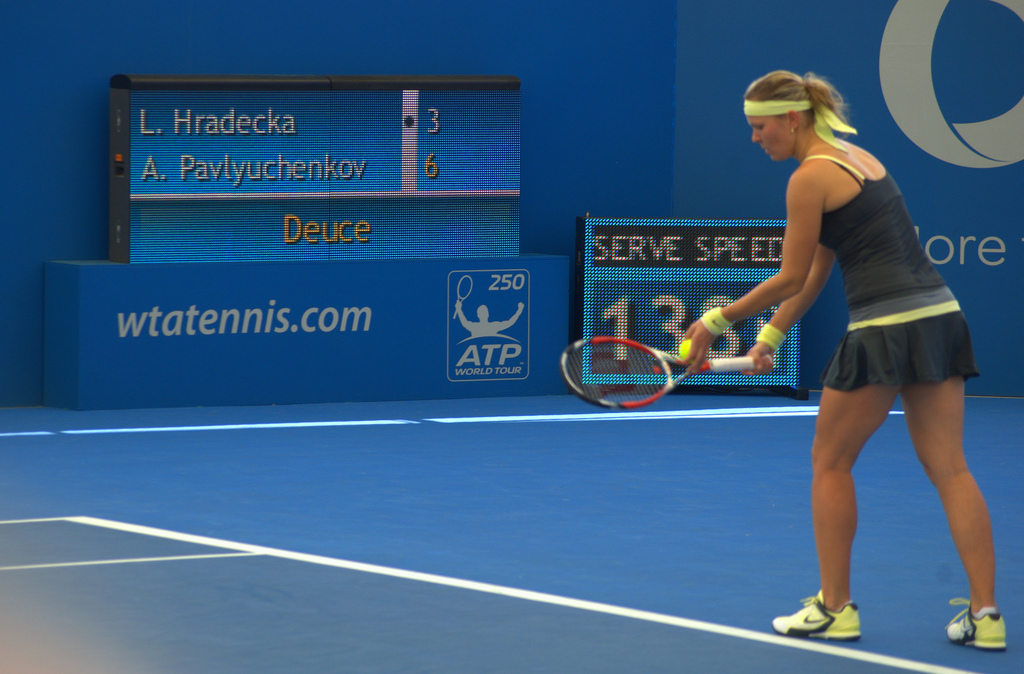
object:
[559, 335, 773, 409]
racket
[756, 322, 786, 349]
headband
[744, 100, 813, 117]
headband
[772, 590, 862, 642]
sneaker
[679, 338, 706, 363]
ball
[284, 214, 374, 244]
word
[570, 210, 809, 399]
sign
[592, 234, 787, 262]
word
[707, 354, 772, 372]
racket handle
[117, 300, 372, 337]
lettering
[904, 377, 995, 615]
leg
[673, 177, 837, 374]
arm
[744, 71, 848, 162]
head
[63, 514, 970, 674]
line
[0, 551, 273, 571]
line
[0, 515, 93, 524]
line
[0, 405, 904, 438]
line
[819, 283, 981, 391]
skirt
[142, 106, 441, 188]
score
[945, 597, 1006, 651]
shoe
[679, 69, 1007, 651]
player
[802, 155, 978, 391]
tennis outfit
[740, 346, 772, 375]
hand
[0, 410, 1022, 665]
tennis court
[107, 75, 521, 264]
sign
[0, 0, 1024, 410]
wall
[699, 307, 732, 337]
wrist band